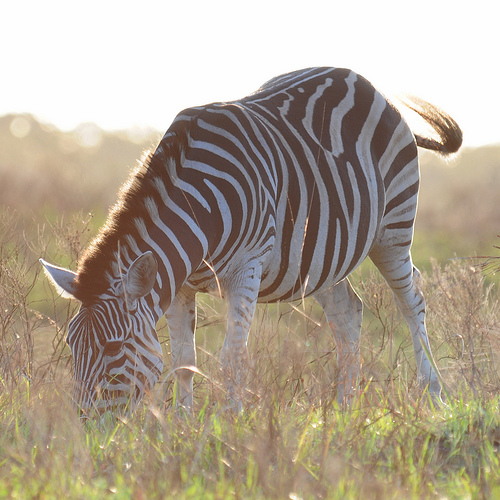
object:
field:
[0, 212, 499, 498]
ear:
[37, 258, 82, 305]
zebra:
[37, 65, 461, 433]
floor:
[0, 285, 500, 388]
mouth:
[68, 388, 158, 436]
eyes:
[63, 333, 72, 351]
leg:
[368, 216, 444, 401]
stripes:
[209, 66, 382, 248]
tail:
[393, 102, 463, 157]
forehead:
[71, 315, 103, 367]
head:
[38, 249, 163, 432]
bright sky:
[0, 0, 500, 130]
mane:
[64, 134, 171, 301]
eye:
[106, 339, 124, 354]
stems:
[363, 250, 500, 395]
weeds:
[0, 199, 500, 389]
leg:
[313, 277, 364, 406]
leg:
[163, 290, 198, 418]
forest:
[2, 204, 499, 500]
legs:
[218, 271, 262, 416]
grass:
[0, 251, 500, 499]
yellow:
[0, 383, 500, 500]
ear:
[114, 251, 160, 315]